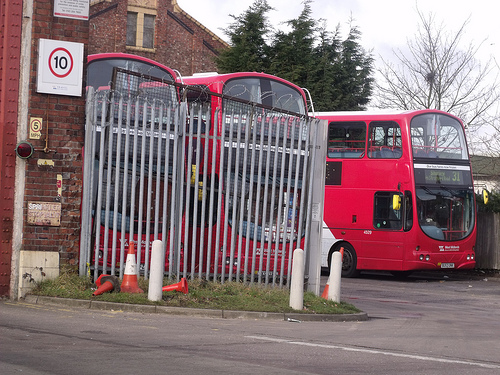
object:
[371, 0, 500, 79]
cloud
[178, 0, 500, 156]
sky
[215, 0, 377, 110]
tree tops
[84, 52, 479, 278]
busses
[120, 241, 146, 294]
pylon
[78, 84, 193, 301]
poles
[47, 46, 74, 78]
circle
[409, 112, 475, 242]
windows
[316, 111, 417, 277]
side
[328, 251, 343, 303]
post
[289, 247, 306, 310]
post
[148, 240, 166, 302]
post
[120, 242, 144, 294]
cone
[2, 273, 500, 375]
ground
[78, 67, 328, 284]
fence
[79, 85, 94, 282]
posts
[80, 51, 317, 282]
buses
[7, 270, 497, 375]
lot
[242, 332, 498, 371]
lines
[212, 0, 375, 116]
tree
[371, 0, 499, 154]
tree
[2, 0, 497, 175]
distance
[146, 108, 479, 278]
bus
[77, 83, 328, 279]
gates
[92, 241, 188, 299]
cones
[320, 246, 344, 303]
cone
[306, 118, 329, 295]
pole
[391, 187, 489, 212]
mirrors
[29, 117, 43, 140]
sign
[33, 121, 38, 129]
5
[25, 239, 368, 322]
median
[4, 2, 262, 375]
left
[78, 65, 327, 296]
fencing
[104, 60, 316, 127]
wire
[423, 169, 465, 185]
sign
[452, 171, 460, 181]
31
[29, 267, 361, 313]
grass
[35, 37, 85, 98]
sign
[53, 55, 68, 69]
10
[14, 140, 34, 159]
light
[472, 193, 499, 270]
portion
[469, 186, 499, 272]
fence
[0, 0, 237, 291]
building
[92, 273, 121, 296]
cone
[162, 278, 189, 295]
cone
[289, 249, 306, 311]
pole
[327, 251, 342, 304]
pole